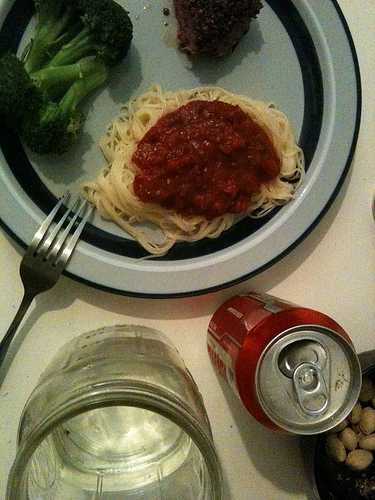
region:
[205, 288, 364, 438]
RED CAN OF SODA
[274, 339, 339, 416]
FLIP TOP AREA OF CAN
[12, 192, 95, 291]
PART OF SERVING FORK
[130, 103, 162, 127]
PART OF COOKED PASTA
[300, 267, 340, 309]
PART OF WHITE TABLE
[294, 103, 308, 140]
PART OF PLATE RIM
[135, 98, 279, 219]
Spaghetti sauce.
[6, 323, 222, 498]
Wide mouth mason jar.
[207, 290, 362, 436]
Opened red soda can.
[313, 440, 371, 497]
Pistachios in a bowl.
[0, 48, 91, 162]
Broccoli on white plate.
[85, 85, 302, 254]
Spaghetti with sauce on it.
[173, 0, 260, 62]
Small piece of steak on a white plate.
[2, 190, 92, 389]
Metal fork on a plate.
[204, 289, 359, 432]
Red soda can.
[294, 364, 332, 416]
Aluminum tab from a soda can.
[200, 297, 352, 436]
red aluminum can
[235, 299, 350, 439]
can is open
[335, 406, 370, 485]
partial view of a dish of nuts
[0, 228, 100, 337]
silver fork set on plate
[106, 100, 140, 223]
angel string noodles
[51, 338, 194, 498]
clear mason jar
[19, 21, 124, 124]
side dish of brocolli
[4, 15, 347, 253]
plate of food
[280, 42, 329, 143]
inner black rim on plate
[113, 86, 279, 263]
spaghetti on the plate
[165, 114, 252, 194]
red sauce on the spaghetti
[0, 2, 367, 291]
a plate of food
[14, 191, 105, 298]
a silver fork on the plate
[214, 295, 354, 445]
a can of soda on the table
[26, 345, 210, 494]
a glass on the table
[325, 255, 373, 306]
the white table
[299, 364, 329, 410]
the tab on the can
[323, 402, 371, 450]
some nuts on the table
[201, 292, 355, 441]
red drink can on the table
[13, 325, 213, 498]
mason jar with no lid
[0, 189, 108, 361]
fork resing on the plate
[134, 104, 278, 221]
sauce on the spaghetti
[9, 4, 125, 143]
broccoli on the plate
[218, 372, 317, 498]
shadow of the drink can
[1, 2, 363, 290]
white plate with black rings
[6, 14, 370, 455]
table the food is on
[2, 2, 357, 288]
plate the food is on